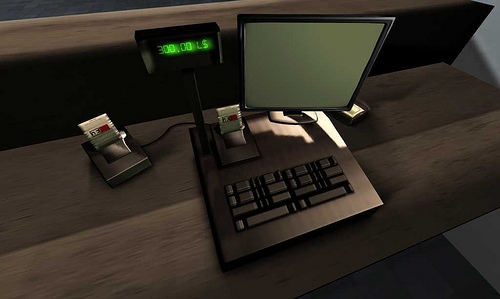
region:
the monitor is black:
[204, 15, 372, 137]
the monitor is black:
[214, 17, 354, 88]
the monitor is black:
[230, 7, 443, 163]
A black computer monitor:
[231, 10, 396, 127]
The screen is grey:
[233, 10, 383, 118]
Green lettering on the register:
[126, 20, 238, 77]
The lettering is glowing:
[141, 18, 229, 72]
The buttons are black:
[191, 122, 366, 250]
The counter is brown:
[35, 52, 470, 282]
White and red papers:
[71, 116, 140, 148]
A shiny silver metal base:
[75, 125, 157, 192]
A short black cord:
[118, 102, 195, 171]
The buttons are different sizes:
[221, 140, 346, 240]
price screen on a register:
[134, 21, 220, 71]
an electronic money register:
[73, 0, 410, 282]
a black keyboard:
[220, 142, 355, 243]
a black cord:
[146, 124, 192, 153]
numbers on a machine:
[151, 37, 216, 57]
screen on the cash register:
[237, 12, 369, 111]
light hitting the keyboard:
[248, 112, 344, 149]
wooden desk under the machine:
[401, 77, 463, 171]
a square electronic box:
[80, 91, 155, 206]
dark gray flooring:
[405, 247, 465, 284]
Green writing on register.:
[143, 30, 283, 122]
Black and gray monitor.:
[233, 17, 438, 177]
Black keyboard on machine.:
[202, 140, 312, 237]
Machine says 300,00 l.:
[128, 22, 225, 84]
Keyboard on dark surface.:
[165, 132, 357, 291]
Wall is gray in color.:
[471, 40, 496, 77]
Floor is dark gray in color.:
[408, 253, 433, 289]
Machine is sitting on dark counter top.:
[108, 127, 453, 277]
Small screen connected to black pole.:
[141, 31, 266, 82]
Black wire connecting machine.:
[123, 112, 221, 199]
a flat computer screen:
[243, 17, 390, 106]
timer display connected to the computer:
[139, 29, 221, 63]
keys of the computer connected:
[226, 146, 371, 224]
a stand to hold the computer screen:
[271, 106, 320, 125]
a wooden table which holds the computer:
[8, 162, 417, 290]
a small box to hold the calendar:
[76, 111, 155, 180]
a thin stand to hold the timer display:
[185, 75, 216, 160]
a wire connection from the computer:
[140, 120, 199, 149]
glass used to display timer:
[164, 42, 214, 52]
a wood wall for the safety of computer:
[7, 0, 488, 100]